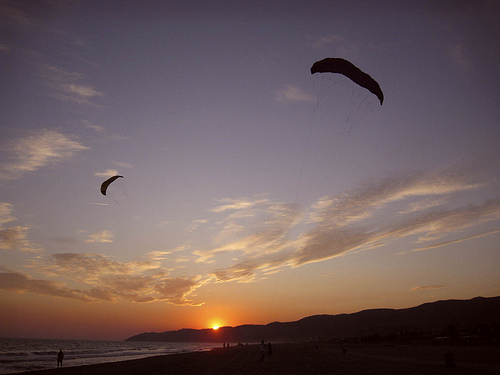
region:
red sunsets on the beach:
[35, 123, 313, 363]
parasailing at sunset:
[50, 143, 276, 355]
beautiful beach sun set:
[22, 302, 304, 369]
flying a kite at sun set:
[51, 131, 256, 339]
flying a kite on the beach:
[68, 143, 324, 371]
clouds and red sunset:
[42, 209, 310, 346]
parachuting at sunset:
[260, 58, 387, 291]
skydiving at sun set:
[48, 62, 388, 357]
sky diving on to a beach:
[27, 66, 439, 367]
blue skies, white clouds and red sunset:
[52, 201, 336, 346]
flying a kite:
[30, 132, 202, 374]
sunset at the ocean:
[5, 278, 493, 374]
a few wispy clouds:
[0, 0, 498, 305]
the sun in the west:
[117, 301, 332, 374]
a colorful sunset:
[79, 268, 379, 374]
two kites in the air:
[61, 28, 418, 258]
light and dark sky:
[6, 0, 495, 270]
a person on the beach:
[27, 328, 109, 374]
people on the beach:
[196, 324, 282, 362]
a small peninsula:
[104, 310, 274, 355]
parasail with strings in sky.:
[299, 48, 399, 183]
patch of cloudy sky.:
[125, 172, 297, 277]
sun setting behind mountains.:
[142, 313, 247, 340]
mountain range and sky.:
[232, 293, 497, 325]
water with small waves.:
[2, 339, 257, 372]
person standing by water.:
[6, 330, 225, 373]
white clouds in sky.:
[8, 249, 178, 302]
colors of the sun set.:
[2, 305, 390, 343]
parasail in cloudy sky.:
[95, 169, 165, 291]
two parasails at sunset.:
[22, 55, 489, 365]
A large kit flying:
[305, 55, 386, 109]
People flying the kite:
[252, 333, 290, 352]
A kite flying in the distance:
[80, 163, 135, 209]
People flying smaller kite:
[216, 338, 256, 355]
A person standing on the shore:
[46, 338, 71, 369]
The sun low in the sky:
[202, 316, 228, 333]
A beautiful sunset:
[0, 200, 499, 330]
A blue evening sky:
[131, 0, 288, 152]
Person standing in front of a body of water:
[0, 335, 197, 373]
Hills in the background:
[131, 294, 499, 338]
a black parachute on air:
[284, 28, 392, 128]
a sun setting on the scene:
[205, 306, 248, 343]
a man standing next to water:
[33, 337, 72, 371]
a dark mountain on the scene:
[308, 294, 484, 354]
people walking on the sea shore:
[211, 336, 291, 366]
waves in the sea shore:
[97, 337, 134, 356]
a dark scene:
[47, 127, 451, 370]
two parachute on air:
[64, 57, 389, 251]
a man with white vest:
[254, 342, 270, 352]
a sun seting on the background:
[188, 322, 224, 339]